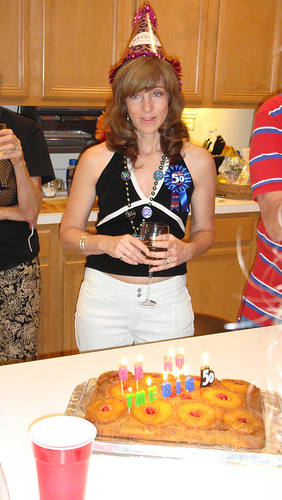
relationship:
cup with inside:
[28, 414, 97, 498] [42, 413, 77, 430]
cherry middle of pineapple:
[146, 405, 155, 417] [177, 401, 214, 426]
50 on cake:
[200, 366, 215, 388] [86, 354, 280, 442]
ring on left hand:
[164, 259, 170, 265] [147, 234, 179, 272]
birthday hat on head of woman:
[108, 4, 182, 82] [58, 1, 213, 348]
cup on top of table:
[28, 414, 97, 498] [6, 326, 277, 485]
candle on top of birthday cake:
[176, 379, 182, 394] [84, 365, 266, 450]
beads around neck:
[120, 144, 166, 239] [129, 125, 162, 157]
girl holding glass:
[59, 0, 216, 353] [139, 222, 170, 310]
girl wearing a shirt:
[59, 0, 216, 353] [104, 182, 137, 215]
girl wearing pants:
[59, 0, 216, 353] [72, 266, 198, 352]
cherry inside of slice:
[214, 391, 226, 399] [222, 408, 262, 433]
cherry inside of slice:
[237, 416, 247, 423] [178, 401, 216, 427]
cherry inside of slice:
[189, 408, 200, 416] [132, 396, 172, 425]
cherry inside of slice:
[144, 405, 153, 415] [86, 397, 125, 424]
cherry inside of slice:
[100, 405, 108, 412] [201, 387, 244, 409]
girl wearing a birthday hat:
[59, 0, 216, 353] [108, 4, 182, 82]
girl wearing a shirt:
[59, 0, 216, 353] [84, 127, 196, 281]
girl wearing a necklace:
[59, 0, 216, 353] [119, 144, 168, 238]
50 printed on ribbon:
[170, 171, 184, 183] [160, 162, 194, 214]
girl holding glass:
[59, 0, 216, 353] [136, 221, 171, 306]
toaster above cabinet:
[21, 110, 103, 152] [39, 213, 261, 351]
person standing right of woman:
[225, 62, 281, 333] [58, 0, 247, 355]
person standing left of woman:
[2, 90, 65, 361] [58, 0, 247, 355]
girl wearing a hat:
[59, 0, 216, 353] [99, 7, 208, 92]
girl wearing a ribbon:
[59, 0, 216, 353] [156, 160, 205, 228]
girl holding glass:
[59, 0, 216, 353] [135, 222, 170, 310]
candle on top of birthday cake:
[197, 364, 217, 388] [84, 365, 266, 450]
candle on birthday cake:
[125, 385, 133, 411] [91, 365, 265, 450]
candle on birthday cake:
[135, 384, 145, 407] [91, 365, 265, 450]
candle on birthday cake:
[148, 386, 157, 404] [91, 365, 265, 450]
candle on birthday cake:
[162, 380, 171, 398] [91, 365, 265, 450]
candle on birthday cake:
[175, 376, 183, 392] [91, 365, 265, 450]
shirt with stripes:
[248, 94, 279, 323] [237, 119, 277, 197]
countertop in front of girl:
[36, 192, 259, 227] [59, 0, 216, 353]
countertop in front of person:
[36, 192, 259, 227] [0, 89, 56, 365]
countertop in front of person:
[36, 192, 259, 227] [233, 78, 281, 331]